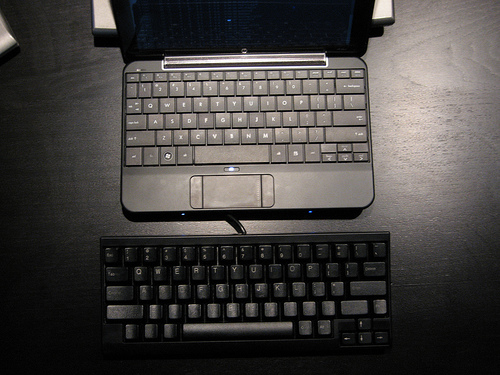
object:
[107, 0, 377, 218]
laptop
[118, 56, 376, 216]
keyboard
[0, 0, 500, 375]
table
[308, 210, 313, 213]
light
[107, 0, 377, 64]
screen